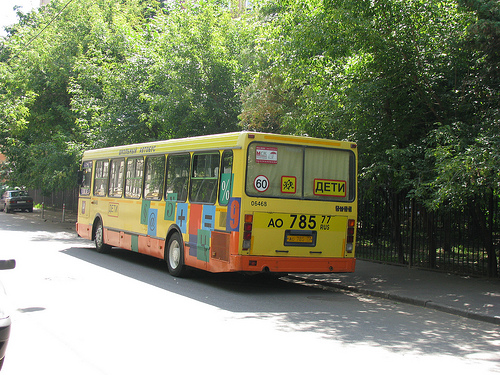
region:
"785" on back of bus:
[288, 213, 320, 233]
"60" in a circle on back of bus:
[249, 171, 271, 197]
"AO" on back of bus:
[263, 213, 286, 235]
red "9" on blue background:
[226, 194, 243, 234]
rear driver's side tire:
[161, 222, 186, 281]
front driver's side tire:
[86, 218, 111, 248]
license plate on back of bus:
[281, 226, 318, 246]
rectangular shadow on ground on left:
[14, 298, 48, 318]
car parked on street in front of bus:
[0, 186, 37, 216]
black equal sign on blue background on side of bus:
[199, 203, 217, 233]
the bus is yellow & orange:
[66, 121, 381, 293]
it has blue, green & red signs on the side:
[112, 184, 221, 274]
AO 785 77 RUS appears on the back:
[256, 201, 341, 234]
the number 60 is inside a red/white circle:
[247, 174, 271, 196]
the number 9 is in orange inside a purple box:
[224, 191, 254, 241]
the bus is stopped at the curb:
[63, 120, 401, 301]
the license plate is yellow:
[282, 230, 323, 247]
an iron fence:
[371, 189, 498, 271]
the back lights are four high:
[241, 209, 255, 265]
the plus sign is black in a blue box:
[177, 205, 187, 234]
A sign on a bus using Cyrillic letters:
[313, 178, 345, 197]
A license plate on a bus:
[283, 230, 316, 246]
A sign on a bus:
[252, 175, 270, 191]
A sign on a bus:
[281, 176, 298, 193]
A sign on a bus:
[256, 145, 279, 163]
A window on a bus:
[244, 140, 355, 202]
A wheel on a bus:
[166, 232, 192, 277]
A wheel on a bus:
[92, 220, 110, 252]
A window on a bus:
[188, 149, 220, 205]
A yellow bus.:
[77, 130, 359, 282]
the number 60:
[239, 165, 292, 217]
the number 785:
[273, 200, 325, 237]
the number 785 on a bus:
[278, 203, 323, 240]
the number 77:
[317, 205, 343, 236]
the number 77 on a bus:
[318, 213, 343, 238]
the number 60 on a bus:
[231, 173, 290, 208]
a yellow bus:
[48, 115, 382, 327]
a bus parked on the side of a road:
[42, 131, 432, 348]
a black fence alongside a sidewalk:
[324, 157, 495, 286]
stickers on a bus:
[226, 130, 371, 273]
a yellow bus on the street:
[60, 123, 383, 324]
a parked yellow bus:
[49, 121, 396, 300]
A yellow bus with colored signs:
[49, 129, 391, 283]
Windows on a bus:
[72, 148, 239, 204]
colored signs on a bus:
[132, 192, 250, 266]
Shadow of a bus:
[66, 230, 340, 325]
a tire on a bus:
[161, 215, 188, 280]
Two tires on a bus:
[77, 206, 224, 268]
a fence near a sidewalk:
[351, 166, 494, 281]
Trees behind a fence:
[176, 3, 499, 261]